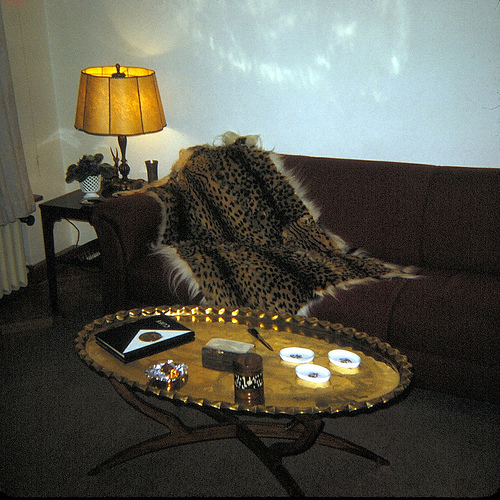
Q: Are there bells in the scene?
A: No, there are no bells.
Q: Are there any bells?
A: No, there are no bells.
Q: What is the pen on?
A: The pen is on the table.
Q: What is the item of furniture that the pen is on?
A: The piece of furniture is a table.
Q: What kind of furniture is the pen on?
A: The pen is on the table.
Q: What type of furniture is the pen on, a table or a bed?
A: The pen is on a table.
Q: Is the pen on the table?
A: Yes, the pen is on the table.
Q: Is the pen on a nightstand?
A: No, the pen is on the table.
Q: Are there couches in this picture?
A: Yes, there is a couch.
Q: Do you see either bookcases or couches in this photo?
A: Yes, there is a couch.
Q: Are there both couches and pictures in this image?
A: No, there is a couch but no pictures.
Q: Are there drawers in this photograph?
A: No, there are no drawers.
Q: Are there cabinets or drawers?
A: No, there are no drawers or cabinets.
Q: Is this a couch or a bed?
A: This is a couch.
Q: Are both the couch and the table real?
A: Yes, both the couch and the table are real.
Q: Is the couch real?
A: Yes, the couch is real.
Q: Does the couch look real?
A: Yes, the couch is real.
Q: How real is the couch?
A: The couch is real.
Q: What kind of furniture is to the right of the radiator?
A: The piece of furniture is a couch.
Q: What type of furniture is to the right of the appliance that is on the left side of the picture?
A: The piece of furniture is a couch.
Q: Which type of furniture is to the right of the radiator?
A: The piece of furniture is a couch.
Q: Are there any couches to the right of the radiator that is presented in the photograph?
A: Yes, there is a couch to the right of the radiator.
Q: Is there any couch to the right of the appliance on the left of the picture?
A: Yes, there is a couch to the right of the radiator.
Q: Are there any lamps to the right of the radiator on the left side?
A: No, there is a couch to the right of the radiator.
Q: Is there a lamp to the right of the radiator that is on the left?
A: No, there is a couch to the right of the radiator.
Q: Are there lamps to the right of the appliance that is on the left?
A: No, there is a couch to the right of the radiator.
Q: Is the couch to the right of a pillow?
A: No, the couch is to the right of the radiator.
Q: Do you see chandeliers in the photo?
A: No, there are no chandeliers.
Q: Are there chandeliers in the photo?
A: No, there are no chandeliers.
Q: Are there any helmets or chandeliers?
A: No, there are no chandeliers or helmets.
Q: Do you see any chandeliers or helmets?
A: No, there are no chandeliers or helmets.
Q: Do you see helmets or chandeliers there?
A: No, there are no chandeliers or helmets.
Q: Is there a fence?
A: No, there are no fences.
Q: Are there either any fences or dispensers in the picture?
A: No, there are no fences or dispensers.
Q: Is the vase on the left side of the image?
A: Yes, the vase is on the left of the image.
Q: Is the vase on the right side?
A: No, the vase is on the left of the image.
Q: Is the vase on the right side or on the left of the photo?
A: The vase is on the left of the image.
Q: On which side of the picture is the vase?
A: The vase is on the left of the image.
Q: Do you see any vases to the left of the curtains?
A: No, the vase is to the right of the curtains.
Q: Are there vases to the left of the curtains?
A: No, the vase is to the right of the curtains.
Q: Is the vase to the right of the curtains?
A: Yes, the vase is to the right of the curtains.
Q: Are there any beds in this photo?
A: No, there are no beds.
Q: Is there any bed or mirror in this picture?
A: No, there are no beds or mirrors.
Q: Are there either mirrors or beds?
A: No, there are no beds or mirrors.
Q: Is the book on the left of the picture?
A: Yes, the book is on the left of the image.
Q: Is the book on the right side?
A: No, the book is on the left of the image.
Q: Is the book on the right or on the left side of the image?
A: The book is on the left of the image.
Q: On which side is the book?
A: The book is on the left of the image.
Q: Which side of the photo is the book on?
A: The book is on the left of the image.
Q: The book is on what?
A: The book is on the table.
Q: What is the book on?
A: The book is on the table.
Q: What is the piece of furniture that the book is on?
A: The piece of furniture is a table.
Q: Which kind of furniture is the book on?
A: The book is on the table.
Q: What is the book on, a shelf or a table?
A: The book is on a table.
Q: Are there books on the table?
A: Yes, there is a book on the table.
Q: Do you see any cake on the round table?
A: No, there is a book on the table.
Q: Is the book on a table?
A: Yes, the book is on a table.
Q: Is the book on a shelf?
A: No, the book is on a table.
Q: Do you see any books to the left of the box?
A: Yes, there is a book to the left of the box.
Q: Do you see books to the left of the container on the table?
A: Yes, there is a book to the left of the box.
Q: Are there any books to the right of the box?
A: No, the book is to the left of the box.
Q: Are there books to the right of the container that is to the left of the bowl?
A: No, the book is to the left of the box.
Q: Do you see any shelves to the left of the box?
A: No, there is a book to the left of the box.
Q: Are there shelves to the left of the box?
A: No, there is a book to the left of the box.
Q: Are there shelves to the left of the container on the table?
A: No, there is a book to the left of the box.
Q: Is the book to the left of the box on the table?
A: Yes, the book is to the left of the box.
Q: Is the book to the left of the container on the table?
A: Yes, the book is to the left of the box.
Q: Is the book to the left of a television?
A: No, the book is to the left of the box.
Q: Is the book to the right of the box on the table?
A: No, the book is to the left of the box.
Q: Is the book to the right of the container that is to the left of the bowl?
A: No, the book is to the left of the box.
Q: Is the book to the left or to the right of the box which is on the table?
A: The book is to the left of the box.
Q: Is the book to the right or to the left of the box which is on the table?
A: The book is to the left of the box.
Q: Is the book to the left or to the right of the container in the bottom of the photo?
A: The book is to the left of the box.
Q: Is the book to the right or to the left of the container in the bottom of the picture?
A: The book is to the left of the box.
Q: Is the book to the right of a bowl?
A: No, the book is to the left of a bowl.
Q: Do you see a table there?
A: Yes, there is a table.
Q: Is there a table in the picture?
A: Yes, there is a table.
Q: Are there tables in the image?
A: Yes, there is a table.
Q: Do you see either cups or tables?
A: Yes, there is a table.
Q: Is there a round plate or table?
A: Yes, there is a round table.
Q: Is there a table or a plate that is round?
A: Yes, the table is round.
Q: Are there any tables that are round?
A: Yes, there is a round table.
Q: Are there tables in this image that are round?
A: Yes, there is a table that is round.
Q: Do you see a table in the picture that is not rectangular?
A: Yes, there is a round table.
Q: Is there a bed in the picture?
A: No, there are no beds.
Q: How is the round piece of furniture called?
A: The piece of furniture is a table.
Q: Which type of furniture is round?
A: The furniture is a table.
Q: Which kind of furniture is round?
A: The furniture is a table.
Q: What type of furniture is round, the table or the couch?
A: The table is round.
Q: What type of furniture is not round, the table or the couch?
A: The couch is not round.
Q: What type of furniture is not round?
A: The furniture is a couch.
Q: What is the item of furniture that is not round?
A: The piece of furniture is a couch.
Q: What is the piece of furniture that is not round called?
A: The piece of furniture is a couch.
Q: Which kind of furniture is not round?
A: The furniture is a couch.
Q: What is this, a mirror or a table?
A: This is a table.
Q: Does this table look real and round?
A: Yes, the table is real and round.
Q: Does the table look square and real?
A: No, the table is real but round.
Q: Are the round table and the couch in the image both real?
A: Yes, both the table and the couch are real.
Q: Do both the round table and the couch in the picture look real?
A: Yes, both the table and the couch are real.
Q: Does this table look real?
A: Yes, the table is real.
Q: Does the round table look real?
A: Yes, the table is real.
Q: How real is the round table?
A: The table is real.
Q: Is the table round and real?
A: Yes, the table is round and real.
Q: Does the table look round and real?
A: Yes, the table is round and real.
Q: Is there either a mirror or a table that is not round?
A: No, there is a table but it is round.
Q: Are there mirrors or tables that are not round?
A: No, there is a table but it is round.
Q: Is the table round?
A: Yes, the table is round.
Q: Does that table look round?
A: Yes, the table is round.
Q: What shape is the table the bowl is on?
A: The table is round.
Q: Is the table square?
A: No, the table is round.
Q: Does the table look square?
A: No, the table is round.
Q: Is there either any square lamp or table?
A: No, there is a table but it is round.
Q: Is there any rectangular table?
A: No, there is a table but it is round.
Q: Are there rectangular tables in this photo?
A: No, there is a table but it is round.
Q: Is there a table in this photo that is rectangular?
A: No, there is a table but it is round.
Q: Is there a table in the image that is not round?
A: No, there is a table but it is round.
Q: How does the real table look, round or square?
A: The table is round.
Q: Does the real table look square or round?
A: The table is round.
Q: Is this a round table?
A: Yes, this is a round table.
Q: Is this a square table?
A: No, this is a round table.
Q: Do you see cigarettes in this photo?
A: No, there are no cigarettes.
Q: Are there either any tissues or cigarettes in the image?
A: No, there are no cigarettes or tissues.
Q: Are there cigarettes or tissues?
A: No, there are no cigarettes or tissues.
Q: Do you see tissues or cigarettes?
A: No, there are no cigarettes or tissues.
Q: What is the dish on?
A: The dish is on the table.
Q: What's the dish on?
A: The dish is on the table.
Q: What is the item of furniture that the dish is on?
A: The piece of furniture is a table.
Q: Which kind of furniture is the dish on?
A: The dish is on the table.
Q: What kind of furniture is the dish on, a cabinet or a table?
A: The dish is on a table.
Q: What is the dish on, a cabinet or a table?
A: The dish is on a table.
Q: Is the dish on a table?
A: Yes, the dish is on a table.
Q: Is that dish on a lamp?
A: No, the dish is on a table.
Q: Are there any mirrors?
A: No, there are no mirrors.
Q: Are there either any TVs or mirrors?
A: No, there are no mirrors or tvs.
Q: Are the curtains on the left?
A: Yes, the curtains are on the left of the image.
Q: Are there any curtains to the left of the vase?
A: Yes, there are curtains to the left of the vase.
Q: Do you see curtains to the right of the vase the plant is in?
A: No, the curtains are to the left of the vase.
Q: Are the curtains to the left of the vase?
A: Yes, the curtains are to the left of the vase.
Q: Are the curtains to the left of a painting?
A: No, the curtains are to the left of the vase.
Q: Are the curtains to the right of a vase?
A: No, the curtains are to the left of a vase.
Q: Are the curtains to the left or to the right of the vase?
A: The curtains are to the left of the vase.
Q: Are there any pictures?
A: No, there are no pictures.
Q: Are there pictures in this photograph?
A: No, there are no pictures.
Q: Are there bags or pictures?
A: No, there are no pictures or bags.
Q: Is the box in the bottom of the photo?
A: Yes, the box is in the bottom of the image.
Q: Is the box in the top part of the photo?
A: No, the box is in the bottom of the image.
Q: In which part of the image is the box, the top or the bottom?
A: The box is in the bottom of the image.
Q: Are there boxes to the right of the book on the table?
A: Yes, there is a box to the right of the book.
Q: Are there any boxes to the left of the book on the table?
A: No, the box is to the right of the book.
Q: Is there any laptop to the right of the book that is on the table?
A: No, there is a box to the right of the book.